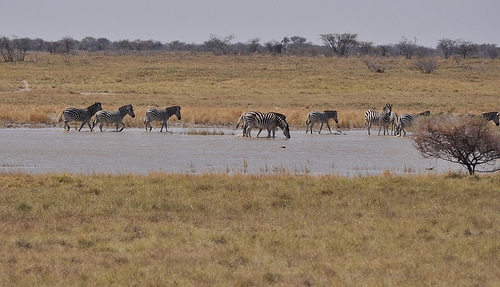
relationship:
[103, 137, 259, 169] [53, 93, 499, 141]
water has zebras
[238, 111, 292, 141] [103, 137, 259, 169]
zebra drinking water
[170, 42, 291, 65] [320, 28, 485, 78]
horizon has trees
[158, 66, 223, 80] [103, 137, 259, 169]
grass behind water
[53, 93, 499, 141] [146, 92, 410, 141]
zebras are in a herd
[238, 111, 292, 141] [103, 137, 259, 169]
zebra in water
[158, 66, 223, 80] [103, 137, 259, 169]
grass growing in water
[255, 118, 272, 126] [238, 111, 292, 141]
stripes on zebra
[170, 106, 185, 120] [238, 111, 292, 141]
head of a zebra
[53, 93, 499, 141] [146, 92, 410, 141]
zebras are in herd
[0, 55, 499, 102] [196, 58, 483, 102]
plain of african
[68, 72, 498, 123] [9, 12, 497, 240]
eight zebras in shot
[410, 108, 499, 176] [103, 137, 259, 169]
bush near water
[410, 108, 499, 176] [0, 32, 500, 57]
bush has horizon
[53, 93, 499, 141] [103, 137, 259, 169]
zebras in water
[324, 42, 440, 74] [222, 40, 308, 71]
bushes on plain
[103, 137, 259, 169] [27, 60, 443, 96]
water by field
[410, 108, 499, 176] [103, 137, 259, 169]
bush by water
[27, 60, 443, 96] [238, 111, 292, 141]
field near zebra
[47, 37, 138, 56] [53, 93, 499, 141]
distance has zebras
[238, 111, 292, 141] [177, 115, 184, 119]
zebra has nose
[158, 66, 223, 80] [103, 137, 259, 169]
grass in water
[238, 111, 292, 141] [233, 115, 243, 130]
zebra has tail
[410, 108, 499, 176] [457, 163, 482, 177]
bush has trunk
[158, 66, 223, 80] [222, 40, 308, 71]
grass on plain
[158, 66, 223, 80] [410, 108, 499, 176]
grass has bush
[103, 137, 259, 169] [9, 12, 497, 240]
water in wild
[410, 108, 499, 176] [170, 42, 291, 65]
bush along horizon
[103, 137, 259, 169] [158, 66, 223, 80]
water has grass